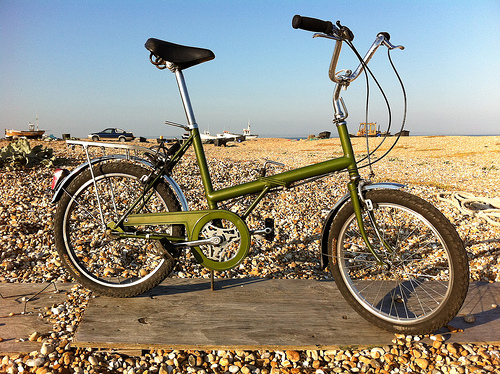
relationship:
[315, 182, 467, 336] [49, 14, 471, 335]
wheel of bike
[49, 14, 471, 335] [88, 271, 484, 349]
bike on table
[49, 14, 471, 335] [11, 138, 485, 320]
bike on rock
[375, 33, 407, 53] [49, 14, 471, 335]
brake of bike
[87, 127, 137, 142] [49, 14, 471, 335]
car behind bike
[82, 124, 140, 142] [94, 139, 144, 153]
car on sand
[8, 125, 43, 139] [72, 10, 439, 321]
sailboat behind bike